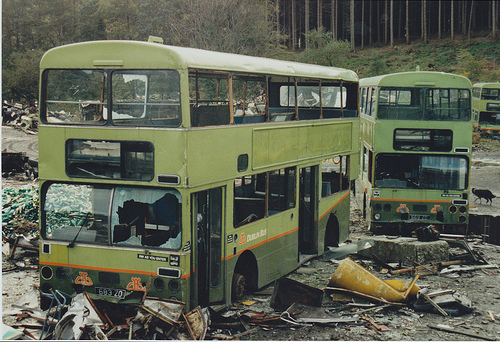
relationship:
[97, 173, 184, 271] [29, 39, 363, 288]
window out of buss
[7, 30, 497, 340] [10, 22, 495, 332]
junk in picture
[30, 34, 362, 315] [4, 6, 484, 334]
bus in junk yard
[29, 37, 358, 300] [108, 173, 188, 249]
bus with windows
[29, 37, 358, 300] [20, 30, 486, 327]
bus in junkyard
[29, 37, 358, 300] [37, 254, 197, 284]
bus with stripe